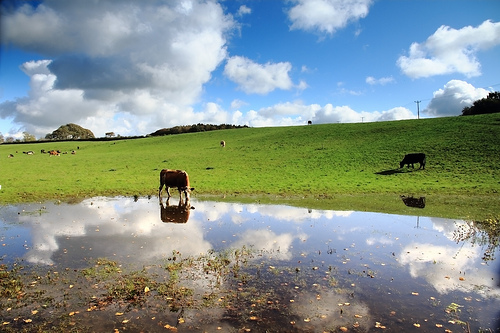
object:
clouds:
[9, 2, 230, 134]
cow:
[153, 166, 198, 209]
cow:
[219, 133, 227, 151]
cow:
[46, 149, 61, 159]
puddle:
[1, 190, 497, 330]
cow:
[154, 167, 194, 202]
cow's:
[157, 167, 192, 206]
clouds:
[79, 23, 163, 82]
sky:
[1, 2, 496, 84]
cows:
[384, 152, 429, 164]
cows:
[153, 163, 189, 205]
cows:
[219, 138, 224, 149]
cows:
[65, 147, 75, 157]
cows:
[36, 146, 45, 154]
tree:
[43, 121, 98, 143]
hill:
[5, 105, 499, 194]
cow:
[398, 150, 426, 171]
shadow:
[373, 162, 412, 176]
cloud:
[393, 17, 499, 80]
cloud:
[284, 0, 373, 36]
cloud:
[0, 2, 230, 133]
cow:
[65, 144, 80, 157]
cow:
[53, 147, 64, 155]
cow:
[35, 149, 48, 154]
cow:
[19, 148, 36, 158]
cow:
[4, 149, 20, 161]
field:
[0, 110, 497, 218]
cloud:
[422, 78, 495, 117]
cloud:
[0, 0, 230, 98]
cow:
[388, 180, 442, 210]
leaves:
[28, 249, 495, 326]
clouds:
[95, 14, 220, 117]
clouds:
[224, 54, 293, 96]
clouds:
[310, 102, 360, 122]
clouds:
[364, 34, 464, 89]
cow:
[304, 117, 315, 124]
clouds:
[127, 17, 314, 118]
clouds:
[45, 93, 87, 121]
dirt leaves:
[86, 270, 174, 316]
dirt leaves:
[6, 269, 72, 327]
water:
[0, 195, 498, 331]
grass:
[0, 114, 499, 216]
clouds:
[185, 50, 310, 128]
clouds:
[12, 1, 369, 121]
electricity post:
[413, 98, 423, 120]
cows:
[8, 139, 86, 158]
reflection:
[160, 201, 191, 223]